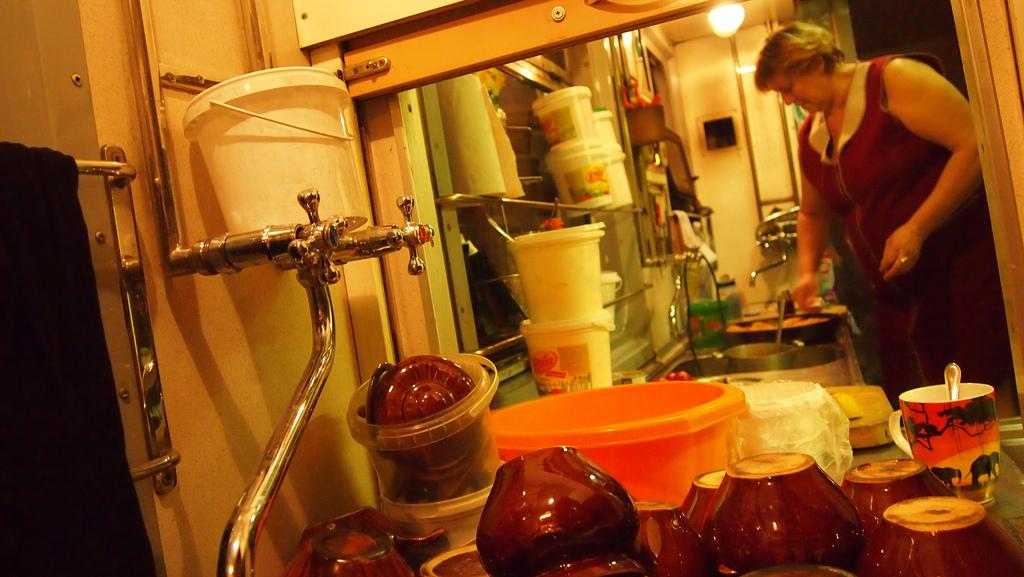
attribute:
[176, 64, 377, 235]
bucket — white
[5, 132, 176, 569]
towel — black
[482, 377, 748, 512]
bowl — orange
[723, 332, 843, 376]
pot — silver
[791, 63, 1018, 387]
dress — red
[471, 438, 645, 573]
cup — brown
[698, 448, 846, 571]
cup — brown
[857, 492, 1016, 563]
cup — brown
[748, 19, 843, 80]
hair — brown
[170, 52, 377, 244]
bucket — white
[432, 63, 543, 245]
paper towel — roll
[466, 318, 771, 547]
plastic bowl — orange